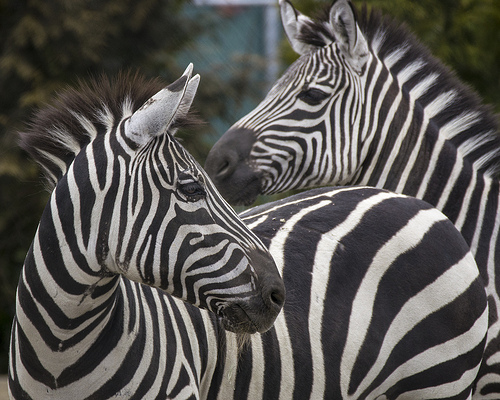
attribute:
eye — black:
[174, 180, 206, 200]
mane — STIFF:
[361, 12, 496, 170]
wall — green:
[217, 24, 258, 46]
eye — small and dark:
[285, 79, 343, 114]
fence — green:
[180, 0, 283, 175]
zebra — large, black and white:
[37, 115, 456, 387]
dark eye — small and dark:
[252, 73, 388, 124]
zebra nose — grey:
[202, 123, 262, 184]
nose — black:
[263, 244, 279, 334]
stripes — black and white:
[51, 223, 113, 400]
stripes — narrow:
[124, 140, 265, 313]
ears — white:
[127, 61, 198, 141]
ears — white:
[274, 1, 367, 64]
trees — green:
[0, 3, 499, 333]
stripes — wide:
[241, 184, 483, 396]